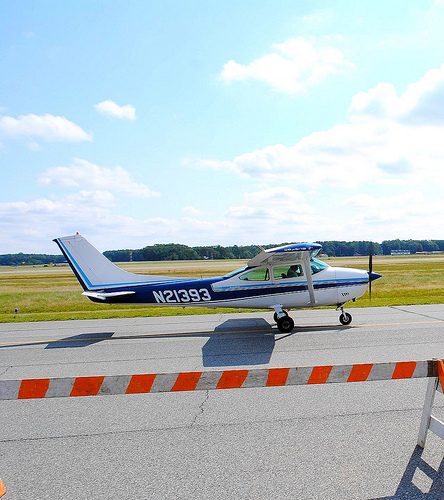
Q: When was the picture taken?
A: Daytime.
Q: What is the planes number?
A: N21393.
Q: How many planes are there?
A: One.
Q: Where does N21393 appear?
A: On the side of the plane.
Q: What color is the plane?
A: Blue and white.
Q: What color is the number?
A: White.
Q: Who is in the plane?
A: The pilot.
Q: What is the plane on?
A: The runway.